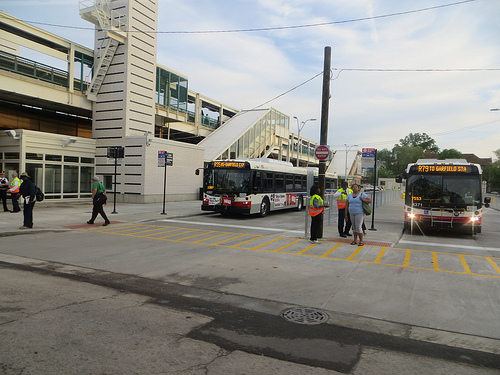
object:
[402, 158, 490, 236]
parked bus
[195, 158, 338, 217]
bus parked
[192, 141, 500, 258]
bus stop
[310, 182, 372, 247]
people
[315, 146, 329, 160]
red/circle sign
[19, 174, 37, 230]
man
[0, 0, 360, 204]
cream building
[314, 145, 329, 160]
red/white sign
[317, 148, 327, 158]
english sign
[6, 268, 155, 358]
gray pavement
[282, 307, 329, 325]
cover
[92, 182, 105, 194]
green shirt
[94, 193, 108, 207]
black bag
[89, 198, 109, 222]
black pants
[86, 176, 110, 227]
man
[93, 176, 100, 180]
gray hair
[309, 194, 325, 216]
orange/green vest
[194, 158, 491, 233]
buses